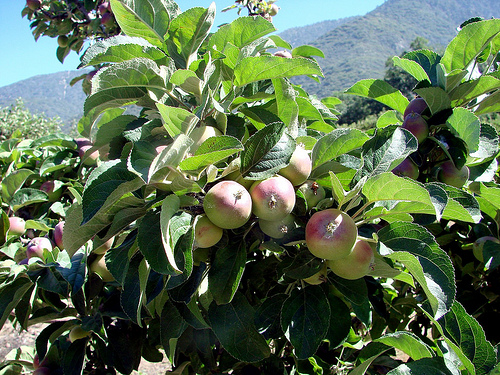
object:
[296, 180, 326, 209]
peach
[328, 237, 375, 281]
peach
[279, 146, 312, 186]
peach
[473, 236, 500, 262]
peach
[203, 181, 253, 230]
peach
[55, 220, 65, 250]
peach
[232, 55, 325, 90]
leaf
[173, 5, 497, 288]
sun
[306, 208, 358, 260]
peach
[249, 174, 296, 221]
peach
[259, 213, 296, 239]
peach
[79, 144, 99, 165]
peach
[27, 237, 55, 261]
peach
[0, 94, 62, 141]
tree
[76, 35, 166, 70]
leaf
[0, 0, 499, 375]
tree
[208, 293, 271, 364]
leaf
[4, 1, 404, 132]
hill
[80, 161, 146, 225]
leaf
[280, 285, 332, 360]
leaf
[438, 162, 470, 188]
peach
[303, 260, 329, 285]
peach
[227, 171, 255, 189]
peach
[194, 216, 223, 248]
peach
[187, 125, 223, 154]
peach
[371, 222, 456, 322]
leaf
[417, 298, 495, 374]
leaf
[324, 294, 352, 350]
leaf